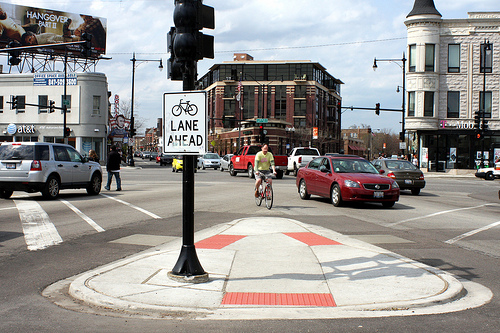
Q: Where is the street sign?
A: On the black pole.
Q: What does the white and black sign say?
A: LANE AHEAD.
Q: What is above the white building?
A: Billboard.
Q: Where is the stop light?
A: On the pole.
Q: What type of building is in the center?
A: Brown building.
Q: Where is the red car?
A: On the road.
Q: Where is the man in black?
A: Crossing the street.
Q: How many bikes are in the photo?
A: 1.